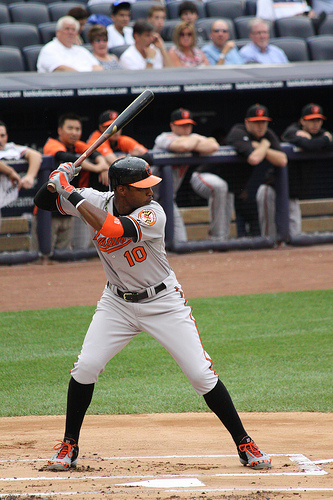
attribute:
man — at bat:
[46, 157, 271, 476]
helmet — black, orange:
[104, 156, 161, 190]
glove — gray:
[46, 171, 84, 212]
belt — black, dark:
[106, 279, 168, 303]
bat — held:
[49, 89, 155, 192]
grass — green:
[2, 287, 331, 419]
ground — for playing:
[2, 243, 330, 498]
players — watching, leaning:
[191, 101, 289, 248]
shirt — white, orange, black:
[32, 176, 173, 291]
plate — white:
[115, 471, 204, 493]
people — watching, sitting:
[35, 16, 101, 74]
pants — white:
[52, 282, 219, 399]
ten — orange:
[117, 244, 148, 268]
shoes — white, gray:
[233, 436, 272, 471]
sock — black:
[201, 377, 248, 449]